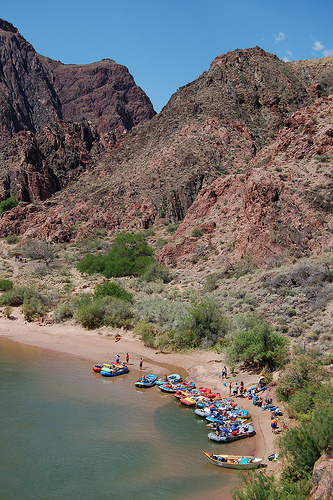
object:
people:
[139, 357, 143, 369]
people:
[126, 352, 130, 363]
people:
[221, 365, 227, 379]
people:
[240, 380, 245, 396]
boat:
[202, 445, 263, 468]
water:
[0, 335, 257, 499]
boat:
[134, 373, 158, 389]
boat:
[100, 362, 129, 377]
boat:
[207, 420, 255, 444]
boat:
[194, 397, 237, 419]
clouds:
[312, 40, 325, 51]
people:
[115, 355, 121, 363]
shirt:
[126, 355, 129, 360]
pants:
[140, 362, 143, 367]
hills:
[0, 17, 157, 213]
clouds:
[274, 30, 287, 44]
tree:
[154, 333, 169, 354]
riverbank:
[0, 305, 299, 500]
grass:
[207, 343, 220, 351]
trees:
[74, 229, 156, 281]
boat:
[92, 362, 121, 373]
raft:
[155, 373, 181, 386]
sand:
[0, 302, 302, 499]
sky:
[0, 0, 333, 117]